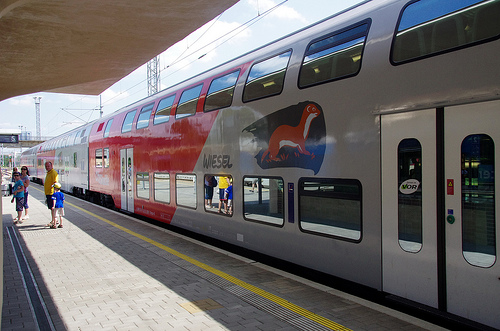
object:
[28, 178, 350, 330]
line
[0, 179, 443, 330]
sidewalk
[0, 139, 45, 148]
bridge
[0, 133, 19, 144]
sign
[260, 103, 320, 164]
animal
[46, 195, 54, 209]
shorts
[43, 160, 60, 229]
man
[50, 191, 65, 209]
shirt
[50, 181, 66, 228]
boy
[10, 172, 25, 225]
man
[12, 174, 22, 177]
glasses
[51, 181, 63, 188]
hat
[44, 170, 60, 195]
shirt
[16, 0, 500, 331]
train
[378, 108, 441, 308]
doors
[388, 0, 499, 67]
window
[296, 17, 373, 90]
window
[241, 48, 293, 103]
window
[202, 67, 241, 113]
window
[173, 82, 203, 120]
window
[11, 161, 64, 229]
family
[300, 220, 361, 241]
seats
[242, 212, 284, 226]
seats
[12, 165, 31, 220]
woman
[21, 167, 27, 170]
sunglasses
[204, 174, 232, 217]
reflection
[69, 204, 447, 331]
shadow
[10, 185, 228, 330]
sun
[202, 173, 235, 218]
window